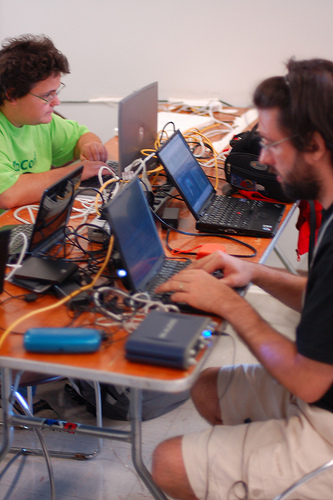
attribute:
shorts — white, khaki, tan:
[187, 357, 329, 499]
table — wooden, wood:
[1, 81, 305, 396]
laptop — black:
[148, 125, 291, 241]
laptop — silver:
[80, 81, 179, 182]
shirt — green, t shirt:
[1, 114, 91, 195]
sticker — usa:
[40, 417, 83, 435]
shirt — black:
[290, 216, 332, 413]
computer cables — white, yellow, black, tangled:
[21, 141, 233, 333]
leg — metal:
[1, 367, 179, 498]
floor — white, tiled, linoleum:
[4, 162, 326, 499]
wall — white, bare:
[3, 3, 332, 149]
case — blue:
[25, 326, 104, 355]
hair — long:
[1, 36, 65, 97]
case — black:
[16, 250, 82, 290]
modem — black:
[221, 134, 299, 198]